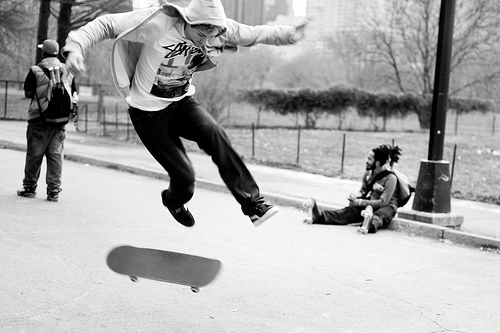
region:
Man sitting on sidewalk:
[308, 143, 408, 233]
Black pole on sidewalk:
[411, 1, 455, 213]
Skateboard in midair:
[106, 244, 223, 294]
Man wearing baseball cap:
[15, 37, 79, 201]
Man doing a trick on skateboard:
[62, 0, 309, 227]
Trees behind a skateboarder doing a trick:
[238, 92, 498, 138]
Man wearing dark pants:
[62, 1, 308, 224]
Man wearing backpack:
[15, 37, 75, 202]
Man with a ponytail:
[308, 143, 413, 232]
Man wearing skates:
[308, 143, 412, 232]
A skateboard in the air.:
[104, 243, 222, 293]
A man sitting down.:
[301, 141, 416, 236]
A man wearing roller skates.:
[301, 145, 416, 237]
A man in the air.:
[59, 0, 312, 229]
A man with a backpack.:
[16, 38, 79, 203]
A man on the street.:
[16, 36, 79, 201]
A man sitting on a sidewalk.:
[0, 118, 497, 253]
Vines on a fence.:
[226, 79, 499, 133]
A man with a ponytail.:
[299, 144, 414, 236]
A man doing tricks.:
[61, 0, 314, 227]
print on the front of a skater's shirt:
[146, 40, 208, 97]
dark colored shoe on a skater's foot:
[244, 201, 283, 226]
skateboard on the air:
[102, 243, 224, 293]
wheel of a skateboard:
[188, 284, 200, 293]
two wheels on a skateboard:
[125, 275, 200, 293]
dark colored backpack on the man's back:
[32, 62, 77, 131]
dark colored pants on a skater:
[126, 93, 273, 216]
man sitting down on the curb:
[298, 141, 416, 234]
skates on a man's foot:
[301, 195, 322, 222]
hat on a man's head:
[34, 40, 59, 55]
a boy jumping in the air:
[79, 6, 309, 249]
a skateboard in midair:
[99, 235, 227, 295]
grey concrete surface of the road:
[269, 252, 369, 318]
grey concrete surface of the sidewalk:
[279, 166, 329, 195]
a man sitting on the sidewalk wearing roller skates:
[286, 143, 411, 247]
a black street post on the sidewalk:
[411, 1, 471, 220]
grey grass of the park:
[294, 123, 331, 158]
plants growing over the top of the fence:
[246, 80, 493, 130]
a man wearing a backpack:
[2, 27, 89, 207]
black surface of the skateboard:
[128, 250, 195, 277]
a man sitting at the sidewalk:
[230, 113, 471, 253]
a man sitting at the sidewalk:
[313, 118, 442, 279]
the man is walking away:
[23, 28, 88, 184]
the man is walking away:
[10, 23, 110, 257]